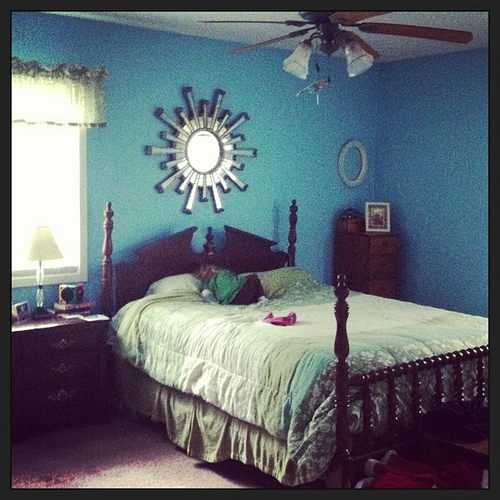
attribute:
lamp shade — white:
[22, 220, 77, 263]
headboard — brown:
[86, 181, 336, 306]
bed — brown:
[98, 194, 487, 489]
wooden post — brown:
[333, 272, 355, 463]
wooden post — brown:
[356, 381, 379, 444]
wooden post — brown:
[383, 376, 400, 427]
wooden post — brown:
[433, 365, 445, 412]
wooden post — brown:
[408, 371, 422, 426]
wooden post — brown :
[360, 381, 374, 453]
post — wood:
[99, 201, 118, 426]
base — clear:
[29, 268, 72, 328]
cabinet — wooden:
[322, 199, 411, 294]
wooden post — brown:
[98, 199, 118, 309]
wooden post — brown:
[287, 197, 302, 267]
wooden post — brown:
[332, 268, 354, 363]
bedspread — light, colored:
[164, 284, 283, 408]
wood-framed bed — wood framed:
[95, 194, 497, 415]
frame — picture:
[364, 200, 394, 238]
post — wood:
[281, 194, 303, 256]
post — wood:
[287, 192, 297, 268]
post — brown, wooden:
[329, 270, 369, 472]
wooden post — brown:
[386, 380, 403, 422]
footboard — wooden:
[356, 335, 486, 455]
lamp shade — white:
[10, 222, 66, 267]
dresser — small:
[331, 207, 408, 297]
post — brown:
[100, 200, 118, 313]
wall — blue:
[13, 12, 373, 344]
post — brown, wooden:
[322, 262, 354, 462]